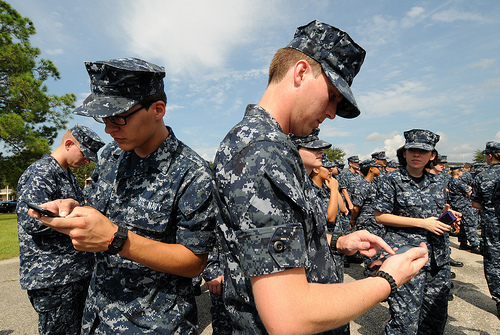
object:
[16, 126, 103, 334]
man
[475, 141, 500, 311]
man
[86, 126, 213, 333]
military uniform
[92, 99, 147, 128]
eye glasses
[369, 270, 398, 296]
black watch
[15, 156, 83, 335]
military uniform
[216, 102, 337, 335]
military uniform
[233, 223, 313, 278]
shirt cuff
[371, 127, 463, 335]
navy member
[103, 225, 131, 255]
watch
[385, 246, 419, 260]
phone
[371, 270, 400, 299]
bracelet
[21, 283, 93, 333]
military pants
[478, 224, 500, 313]
military pants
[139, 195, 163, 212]
branch tape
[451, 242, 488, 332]
shadow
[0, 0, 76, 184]
tree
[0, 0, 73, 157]
leaves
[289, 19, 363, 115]
cap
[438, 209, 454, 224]
phone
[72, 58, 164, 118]
cap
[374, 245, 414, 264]
screen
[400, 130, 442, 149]
cap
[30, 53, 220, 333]
he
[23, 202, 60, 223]
cell phone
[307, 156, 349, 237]
woman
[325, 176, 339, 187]
hand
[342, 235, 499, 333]
asphalt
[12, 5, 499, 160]
clouds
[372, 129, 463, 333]
uniform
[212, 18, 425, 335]
he